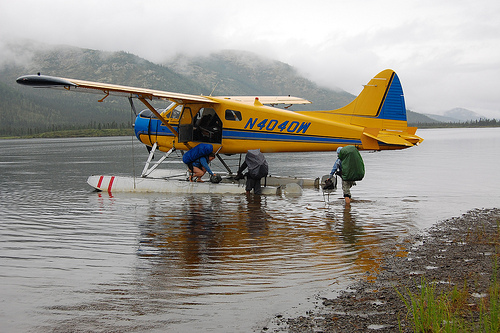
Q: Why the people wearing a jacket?
A: It's cold.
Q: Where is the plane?
A: On the river.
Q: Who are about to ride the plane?
A: People.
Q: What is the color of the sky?
A: White.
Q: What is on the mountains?
A: Fog.